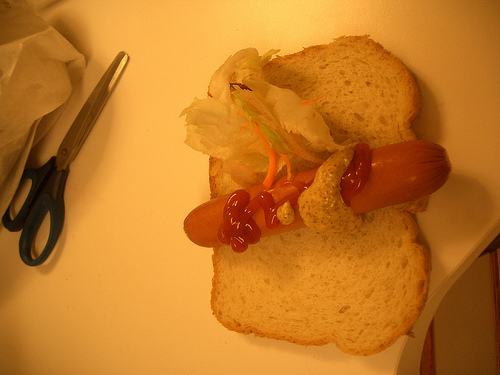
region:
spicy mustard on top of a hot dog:
[284, 141, 366, 247]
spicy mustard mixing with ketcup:
[269, 149, 353, 259]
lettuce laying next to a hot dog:
[196, 101, 341, 191]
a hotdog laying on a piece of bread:
[190, 98, 430, 271]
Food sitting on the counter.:
[201, 56, 403, 371]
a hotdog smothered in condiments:
[188, 128, 440, 257]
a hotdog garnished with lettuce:
[182, 85, 444, 257]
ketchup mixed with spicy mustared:
[199, 175, 429, 271]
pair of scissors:
[2, 35, 140, 282]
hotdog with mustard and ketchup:
[176, 132, 472, 254]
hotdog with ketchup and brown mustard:
[181, 131, 467, 255]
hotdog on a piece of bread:
[181, 34, 467, 352]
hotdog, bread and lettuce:
[175, 23, 445, 355]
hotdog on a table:
[171, 5, 491, 366]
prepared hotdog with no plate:
[173, 28, 440, 358]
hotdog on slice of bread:
[171, 30, 456, 365]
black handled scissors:
[0, 35, 140, 275]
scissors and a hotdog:
[3, 27, 483, 362]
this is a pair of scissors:
[4, 15, 132, 279]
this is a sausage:
[170, 129, 461, 254]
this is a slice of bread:
[186, 19, 429, 348]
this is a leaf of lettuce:
[171, 39, 326, 191]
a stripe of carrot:
[236, 120, 297, 195]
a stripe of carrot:
[269, 128, 297, 188]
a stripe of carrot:
[206, 193, 266, 265]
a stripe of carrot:
[252, 186, 283, 231]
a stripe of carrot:
[284, 171, 315, 223]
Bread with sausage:
[192, 36, 443, 344]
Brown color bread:
[207, 289, 426, 349]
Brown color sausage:
[383, 148, 445, 192]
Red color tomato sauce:
[211, 195, 273, 257]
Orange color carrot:
[259, 145, 279, 183]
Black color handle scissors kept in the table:
[36, 47, 83, 274]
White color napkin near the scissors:
[8, 34, 64, 101]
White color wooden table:
[61, 288, 166, 348]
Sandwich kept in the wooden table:
[165, 38, 442, 373]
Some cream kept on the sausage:
[298, 170, 341, 228]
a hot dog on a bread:
[129, 12, 460, 372]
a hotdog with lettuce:
[207, 23, 479, 373]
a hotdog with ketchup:
[189, 41, 471, 370]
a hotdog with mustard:
[223, 22, 458, 310]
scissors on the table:
[25, 54, 107, 221]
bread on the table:
[176, 40, 478, 346]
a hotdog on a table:
[182, 23, 469, 269]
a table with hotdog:
[24, 29, 495, 335]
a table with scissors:
[14, 26, 282, 366]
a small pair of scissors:
[19, 66, 120, 251]